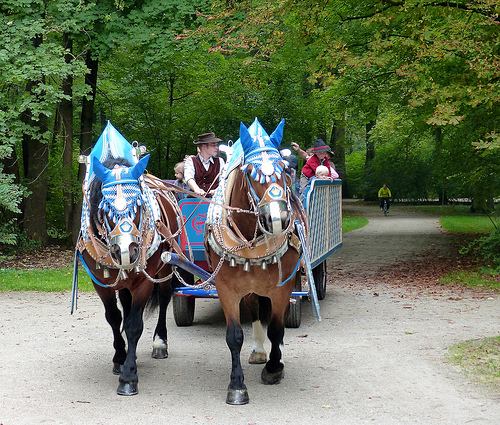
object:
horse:
[72, 150, 184, 397]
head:
[86, 153, 152, 273]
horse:
[202, 117, 312, 405]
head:
[233, 118, 289, 234]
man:
[183, 130, 227, 196]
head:
[192, 129, 223, 156]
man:
[377, 183, 394, 211]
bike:
[377, 193, 391, 215]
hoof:
[116, 367, 141, 395]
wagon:
[173, 177, 341, 327]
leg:
[247, 292, 267, 364]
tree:
[0, 0, 107, 245]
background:
[0, 0, 499, 424]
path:
[0, 193, 499, 424]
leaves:
[373, 289, 381, 297]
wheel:
[172, 270, 194, 326]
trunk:
[328, 116, 348, 197]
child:
[299, 139, 341, 206]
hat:
[191, 131, 223, 145]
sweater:
[303, 154, 331, 178]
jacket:
[188, 155, 220, 197]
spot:
[294, 330, 313, 341]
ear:
[131, 153, 153, 182]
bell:
[117, 265, 130, 279]